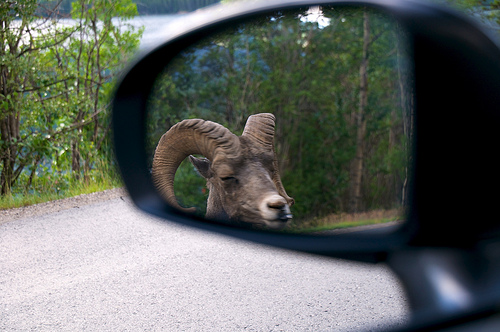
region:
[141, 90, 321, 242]
ram in a sideview mirror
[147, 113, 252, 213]
right horn on a ram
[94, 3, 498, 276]
side view mirror on a car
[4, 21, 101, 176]
green trees along side of road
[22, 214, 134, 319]
street where car is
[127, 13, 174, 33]
water in the background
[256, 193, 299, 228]
nose and mouth of a ram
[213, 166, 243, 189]
right eye of a ram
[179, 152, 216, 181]
ear of a ram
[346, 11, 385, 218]
tree trunk in the mirror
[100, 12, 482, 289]
the mirror is on the car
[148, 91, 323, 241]
you can see the big horn sheep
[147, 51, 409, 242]
the forrest is in the background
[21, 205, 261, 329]
the road is grey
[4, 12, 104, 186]
the trees are green and leafy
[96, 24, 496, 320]
the mirror is on a car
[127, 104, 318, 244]
the sheep is brown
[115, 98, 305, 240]
the sheep has large horns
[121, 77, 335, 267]
the sheep has a white snout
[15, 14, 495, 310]
the car is driving away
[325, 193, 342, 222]
the mirror is clear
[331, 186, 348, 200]
the mirror is clear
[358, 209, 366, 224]
the mirror is clear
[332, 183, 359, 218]
the mirror is clear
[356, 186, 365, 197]
the mirror is clear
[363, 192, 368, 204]
the mirror is clear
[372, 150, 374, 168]
the mirror is clear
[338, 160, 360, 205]
the mirror is clear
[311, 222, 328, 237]
the mirror is clear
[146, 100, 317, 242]
a ram's head reflected in a mirror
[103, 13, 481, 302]
a sideview mirror on a car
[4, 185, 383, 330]
a paved roadway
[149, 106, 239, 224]
a curved ram's horn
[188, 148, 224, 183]
an ear under a horn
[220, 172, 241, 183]
a closed eye on a ram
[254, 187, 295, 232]
the white nose and mouth of a ram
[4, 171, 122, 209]
grass growing along a roadside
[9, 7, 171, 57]
water behind the trees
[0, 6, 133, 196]
trees along a road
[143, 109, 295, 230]
a mountain goat with the eyes closed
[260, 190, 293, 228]
the ram has a white snout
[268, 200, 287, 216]
the nose is black on the ram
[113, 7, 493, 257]
a reflection of the goat in a mirror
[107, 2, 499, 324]
a side view mirror on a vehicle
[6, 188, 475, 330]
the car is on a street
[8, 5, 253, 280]
a river is beside the road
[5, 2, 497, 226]
trees and bushes are on the roadside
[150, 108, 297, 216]
the mountain goat has thick horns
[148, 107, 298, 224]
the ram's horns have ridges